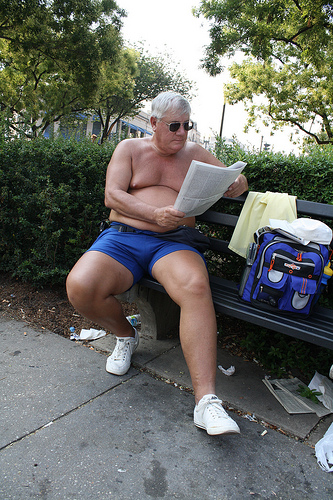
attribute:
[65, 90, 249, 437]
man — reading, topless, sitting, shirtless, whitehaired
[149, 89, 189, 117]
hair — silver, gray, white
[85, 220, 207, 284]
shorts — blue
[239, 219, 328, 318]
bag — blue, grey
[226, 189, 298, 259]
shirt — yellow, folded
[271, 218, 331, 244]
cap — white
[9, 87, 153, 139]
building — grey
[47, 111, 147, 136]
awnings — blue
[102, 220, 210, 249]
fanny pack — dark blue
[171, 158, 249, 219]
newspaper — read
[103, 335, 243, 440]
sneakers — white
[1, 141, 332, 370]
bushes — green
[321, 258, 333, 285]
water bottle — yellow, blue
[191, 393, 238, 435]
tennis shoe — white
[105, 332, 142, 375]
tennis shoe — white